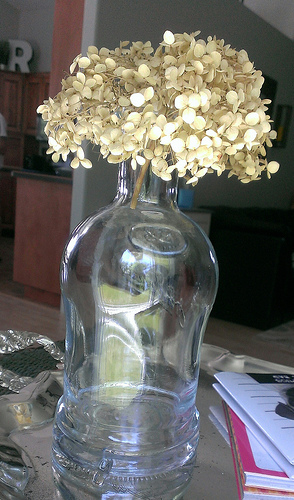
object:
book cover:
[225, 404, 294, 493]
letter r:
[8, 38, 33, 73]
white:
[25, 48, 31, 56]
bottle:
[49, 111, 219, 499]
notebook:
[211, 370, 294, 479]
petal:
[163, 29, 175, 45]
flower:
[35, 28, 281, 189]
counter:
[11, 167, 74, 312]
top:
[17, 167, 73, 183]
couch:
[208, 204, 293, 332]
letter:
[9, 35, 33, 75]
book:
[221, 396, 293, 500]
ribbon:
[0, 320, 168, 396]